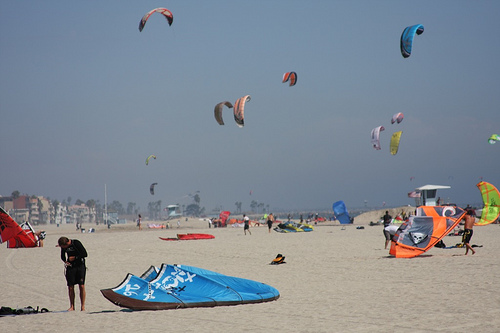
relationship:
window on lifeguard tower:
[425, 187, 437, 197] [417, 182, 452, 208]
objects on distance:
[184, 199, 309, 232] [79, 198, 383, 221]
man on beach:
[461, 203, 476, 257] [307, 221, 419, 329]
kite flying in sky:
[388, 125, 404, 155] [1, 0, 484, 207]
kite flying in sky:
[370, 120, 385, 149] [1, 0, 484, 207]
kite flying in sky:
[388, 108, 405, 125] [1, 0, 484, 207]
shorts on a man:
[61, 258, 90, 283] [51, 235, 98, 315]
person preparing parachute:
[48, 231, 98, 316] [102, 261, 278, 309]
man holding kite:
[463, 199, 476, 249] [399, 212, 442, 252]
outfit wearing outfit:
[240, 211, 257, 237] [240, 211, 257, 237]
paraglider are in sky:
[131, 10, 425, 158] [5, 7, 488, 191]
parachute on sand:
[102, 261, 278, 309] [10, 211, 499, 330]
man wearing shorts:
[53, 236, 91, 306] [62, 259, 91, 288]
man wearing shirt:
[380, 220, 402, 262] [385, 222, 401, 240]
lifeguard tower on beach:
[417, 177, 449, 208] [13, 176, 482, 321]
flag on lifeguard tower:
[406, 189, 425, 206] [421, 168, 449, 223]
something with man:
[61, 255, 73, 277] [58, 237, 90, 311]